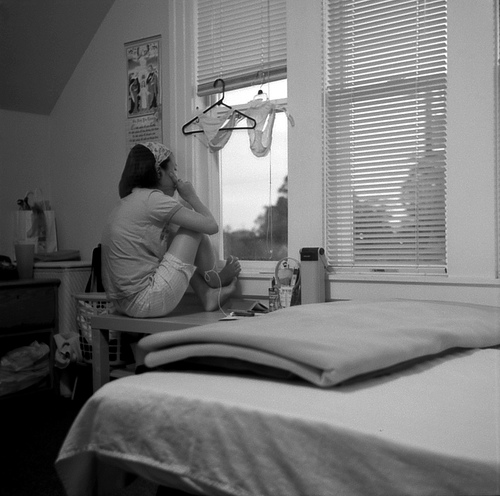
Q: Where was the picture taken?
A: In a bedroom.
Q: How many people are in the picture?
A: 1.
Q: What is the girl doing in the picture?
A: Looking out window.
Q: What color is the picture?
A: Black and white.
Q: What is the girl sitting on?
A: A table.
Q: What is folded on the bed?
A: A blanket.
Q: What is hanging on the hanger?
A: Underwear.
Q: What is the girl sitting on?
A: Table.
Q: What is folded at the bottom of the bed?
A: Blanket.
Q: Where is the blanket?
A: Bed.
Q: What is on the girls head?
A: Bandana.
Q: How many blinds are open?
A: One.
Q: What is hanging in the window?
A: Underwear.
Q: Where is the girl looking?
A: Window.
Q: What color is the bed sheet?
A: White.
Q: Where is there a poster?
A: Wall.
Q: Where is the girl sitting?
A: On a table.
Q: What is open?
A: Blinds.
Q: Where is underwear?
A: On hangers.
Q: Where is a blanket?
A: On a bed.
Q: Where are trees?
A: Out the window.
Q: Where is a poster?
A: On the wall.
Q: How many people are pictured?
A: One.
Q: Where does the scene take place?
A: In a bedroom.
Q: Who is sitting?
A: A girl.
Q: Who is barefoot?
A: The girl.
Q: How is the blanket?
A: Folded.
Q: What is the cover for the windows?
A: Blinds.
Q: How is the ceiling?
A: Sloped.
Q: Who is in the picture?
A: A girl.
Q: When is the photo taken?
A: During the daytime.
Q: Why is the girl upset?
A: She is all alone.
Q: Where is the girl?
A: In her bedroom.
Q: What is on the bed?
A: An extra blanket.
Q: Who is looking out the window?
A: A girl.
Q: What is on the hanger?
A: Some panties.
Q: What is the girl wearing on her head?
A: A scarf.